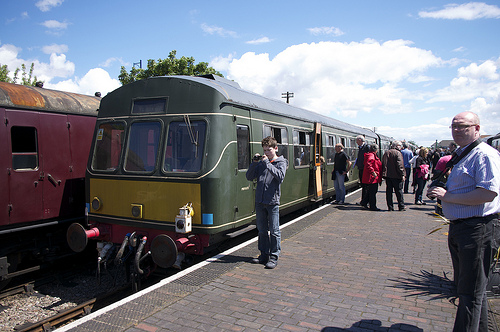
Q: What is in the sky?
A: Clouds.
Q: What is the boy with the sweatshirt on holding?
A: Camera.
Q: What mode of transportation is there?
A: Train.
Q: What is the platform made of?
A: Bricks.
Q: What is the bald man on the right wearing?
A: Glasses.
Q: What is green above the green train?
A: Tree.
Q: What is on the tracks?
A: Trains.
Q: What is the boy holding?
A: A camera.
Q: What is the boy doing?
A: Taking a picture.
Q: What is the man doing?
A: Standing.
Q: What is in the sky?
A: Clouds.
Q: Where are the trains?
A: On the tracks.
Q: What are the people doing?
A: Waiting to board the train.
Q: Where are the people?
A: Train station.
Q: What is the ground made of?
A: Brick.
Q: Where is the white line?
A: On the curb.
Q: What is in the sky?
A: Clouds.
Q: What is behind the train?
A: Tree.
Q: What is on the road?
A: Bricks.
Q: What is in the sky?
A: Clouds.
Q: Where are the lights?
A: On the train.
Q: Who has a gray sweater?
A: Child.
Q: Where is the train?
A: At the station.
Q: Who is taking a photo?
A: Child.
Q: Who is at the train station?
A: Group of people.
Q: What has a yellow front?
A: Train.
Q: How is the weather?
A: Sunny.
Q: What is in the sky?
A: Clouds.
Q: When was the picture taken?
A: Daytime.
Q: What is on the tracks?
A: The train.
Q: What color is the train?
A: Green.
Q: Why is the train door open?
A: So people can get on.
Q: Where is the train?
A: On the tracks.